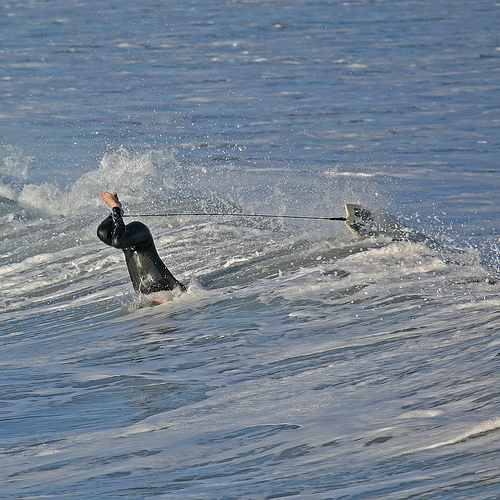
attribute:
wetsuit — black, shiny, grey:
[95, 209, 181, 292]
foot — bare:
[102, 191, 119, 207]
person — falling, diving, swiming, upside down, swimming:
[95, 190, 185, 293]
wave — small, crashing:
[2, 194, 500, 401]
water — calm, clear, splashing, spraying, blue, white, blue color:
[2, 1, 500, 500]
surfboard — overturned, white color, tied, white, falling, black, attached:
[345, 204, 437, 243]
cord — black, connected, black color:
[123, 213, 346, 221]